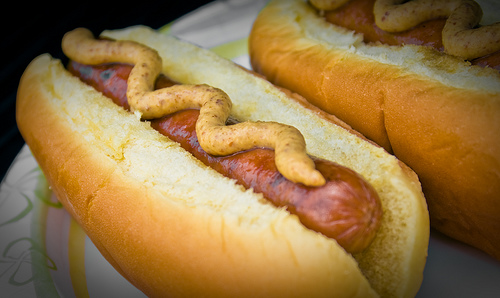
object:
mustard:
[61, 25, 328, 187]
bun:
[16, 25, 431, 297]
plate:
[0, 2, 498, 297]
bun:
[248, 1, 498, 259]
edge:
[275, 0, 500, 93]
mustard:
[305, 0, 500, 61]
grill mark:
[100, 69, 114, 80]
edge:
[0, 1, 111, 298]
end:
[329, 170, 382, 251]